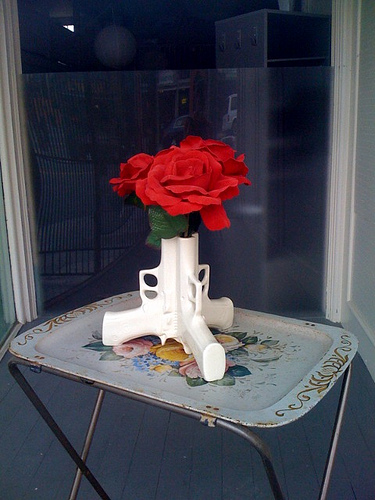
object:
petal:
[200, 202, 234, 232]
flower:
[110, 135, 251, 232]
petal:
[181, 193, 221, 205]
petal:
[136, 179, 160, 206]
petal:
[216, 159, 249, 174]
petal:
[127, 153, 154, 180]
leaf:
[125, 190, 189, 249]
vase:
[102, 232, 235, 381]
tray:
[9, 290, 358, 429]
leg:
[321, 362, 354, 499]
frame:
[323, 0, 359, 326]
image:
[80, 325, 286, 386]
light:
[95, 25, 137, 68]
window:
[18, 2, 332, 313]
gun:
[176, 237, 226, 382]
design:
[276, 332, 352, 416]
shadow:
[266, 67, 327, 245]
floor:
[0, 310, 375, 499]